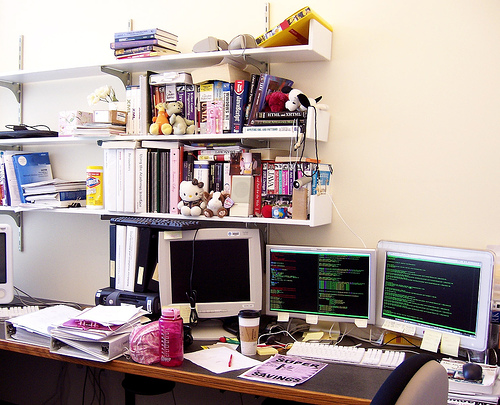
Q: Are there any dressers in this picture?
A: No, there are no dressers.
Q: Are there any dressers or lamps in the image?
A: No, there are no dressers or lamps.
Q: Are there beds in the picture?
A: No, there are no beds.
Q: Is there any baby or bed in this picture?
A: No, there are no beds or babies.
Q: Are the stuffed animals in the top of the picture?
A: Yes, the stuffed animals are in the top of the image.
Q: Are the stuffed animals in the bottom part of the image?
A: No, the stuffed animals are in the top of the image.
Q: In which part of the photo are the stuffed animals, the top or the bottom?
A: The stuffed animals are in the top of the image.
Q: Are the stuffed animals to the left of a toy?
A: Yes, the stuffed animals are to the left of a toy.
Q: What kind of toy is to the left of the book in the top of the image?
A: The toys are stuffed animals.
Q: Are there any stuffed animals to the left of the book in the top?
A: Yes, there are stuffed animals to the left of the book.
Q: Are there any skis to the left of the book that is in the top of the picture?
A: No, there are stuffed animals to the left of the book.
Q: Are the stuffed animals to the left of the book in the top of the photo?
A: Yes, the stuffed animals are to the left of the book.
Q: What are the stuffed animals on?
A: The stuffed animals are on the shelf.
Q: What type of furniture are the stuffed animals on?
A: The stuffed animals are on the shelf.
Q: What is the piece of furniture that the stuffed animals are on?
A: The piece of furniture is a shelf.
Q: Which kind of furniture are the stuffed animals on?
A: The stuffed animals are on the shelf.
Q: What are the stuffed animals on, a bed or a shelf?
A: The stuffed animals are on a shelf.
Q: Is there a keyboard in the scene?
A: Yes, there is a keyboard.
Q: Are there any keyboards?
A: Yes, there is a keyboard.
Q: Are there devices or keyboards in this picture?
A: Yes, there is a keyboard.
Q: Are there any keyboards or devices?
A: Yes, there is a keyboard.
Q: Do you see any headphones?
A: No, there are no headphones.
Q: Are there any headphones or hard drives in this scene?
A: No, there are no headphones or hard drives.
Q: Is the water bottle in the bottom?
A: Yes, the water bottle is in the bottom of the image.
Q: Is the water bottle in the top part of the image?
A: No, the water bottle is in the bottom of the image.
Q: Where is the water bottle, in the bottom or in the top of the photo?
A: The water bottle is in the bottom of the image.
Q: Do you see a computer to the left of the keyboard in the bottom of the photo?
A: No, there is a water bottle to the left of the keyboard.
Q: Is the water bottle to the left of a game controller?
A: No, the water bottle is to the left of the keyboard.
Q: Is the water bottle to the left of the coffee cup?
A: Yes, the water bottle is to the left of the coffee cup.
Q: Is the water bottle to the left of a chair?
A: No, the water bottle is to the left of the coffee cup.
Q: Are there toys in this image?
A: Yes, there is a toy.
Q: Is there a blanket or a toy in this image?
A: Yes, there is a toy.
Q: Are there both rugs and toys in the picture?
A: No, there is a toy but no rugs.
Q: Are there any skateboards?
A: No, there are no skateboards.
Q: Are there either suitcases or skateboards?
A: No, there are no skateboards or suitcases.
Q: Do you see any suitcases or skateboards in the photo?
A: No, there are no skateboards or suitcases.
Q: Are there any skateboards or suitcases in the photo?
A: No, there are no skateboards or suitcases.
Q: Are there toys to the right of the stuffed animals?
A: Yes, there is a toy to the right of the stuffed animals.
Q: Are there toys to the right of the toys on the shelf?
A: Yes, there is a toy to the right of the stuffed animals.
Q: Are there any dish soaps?
A: No, there are no dish soaps.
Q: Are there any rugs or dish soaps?
A: No, there are no dish soaps or rugs.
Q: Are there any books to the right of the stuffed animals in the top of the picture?
A: Yes, there is a book to the right of the stuffed animals.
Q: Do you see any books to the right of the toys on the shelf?
A: Yes, there is a book to the right of the stuffed animals.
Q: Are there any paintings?
A: No, there are no paintings.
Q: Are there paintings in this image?
A: No, there are no paintings.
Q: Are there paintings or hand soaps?
A: No, there are no paintings or hand soaps.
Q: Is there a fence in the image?
A: No, there are no fences.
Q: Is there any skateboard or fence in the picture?
A: No, there are no fences or skateboards.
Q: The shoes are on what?
A: The shoes are on the shelf.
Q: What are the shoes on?
A: The shoes are on the shelf.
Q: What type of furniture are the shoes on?
A: The shoes are on the shelf.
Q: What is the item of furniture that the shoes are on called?
A: The piece of furniture is a shelf.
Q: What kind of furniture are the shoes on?
A: The shoes are on the shelf.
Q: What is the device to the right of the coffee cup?
A: The device is a screen.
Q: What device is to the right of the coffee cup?
A: The device is a screen.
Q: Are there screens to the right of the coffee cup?
A: Yes, there is a screen to the right of the coffee cup.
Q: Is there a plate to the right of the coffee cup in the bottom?
A: No, there is a screen to the right of the coffee cup.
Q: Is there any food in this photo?
A: No, there is no food.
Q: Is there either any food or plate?
A: No, there are no food or plates.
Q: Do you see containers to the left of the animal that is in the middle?
A: Yes, there is a container to the left of the animal.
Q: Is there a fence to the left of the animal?
A: No, there is a container to the left of the animal.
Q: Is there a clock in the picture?
A: No, there are no clocks.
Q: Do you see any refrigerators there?
A: No, there are no refrigerators.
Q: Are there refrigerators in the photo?
A: No, there are no refrigerators.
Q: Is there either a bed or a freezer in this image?
A: No, there are no refrigerators or beds.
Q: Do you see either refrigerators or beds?
A: No, there are no refrigerators or beds.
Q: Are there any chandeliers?
A: No, there are no chandeliers.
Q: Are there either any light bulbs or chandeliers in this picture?
A: No, there are no chandeliers or light bulbs.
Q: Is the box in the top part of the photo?
A: Yes, the box is in the top of the image.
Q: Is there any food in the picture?
A: No, there is no food.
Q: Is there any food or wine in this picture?
A: No, there are no food or wines.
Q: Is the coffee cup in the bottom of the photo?
A: Yes, the coffee cup is in the bottom of the image.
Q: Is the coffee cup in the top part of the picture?
A: No, the coffee cup is in the bottom of the image.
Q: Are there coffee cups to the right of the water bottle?
A: Yes, there is a coffee cup to the right of the water bottle.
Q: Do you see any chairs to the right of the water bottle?
A: No, there is a coffee cup to the right of the water bottle.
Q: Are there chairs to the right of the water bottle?
A: No, there is a coffee cup to the right of the water bottle.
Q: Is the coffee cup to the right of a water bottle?
A: Yes, the coffee cup is to the right of a water bottle.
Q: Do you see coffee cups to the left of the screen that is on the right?
A: Yes, there is a coffee cup to the left of the screen.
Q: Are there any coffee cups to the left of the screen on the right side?
A: Yes, there is a coffee cup to the left of the screen.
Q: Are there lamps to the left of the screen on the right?
A: No, there is a coffee cup to the left of the screen.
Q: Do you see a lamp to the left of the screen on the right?
A: No, there is a coffee cup to the left of the screen.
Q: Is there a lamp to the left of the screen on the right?
A: No, there is a coffee cup to the left of the screen.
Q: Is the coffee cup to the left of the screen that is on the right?
A: Yes, the coffee cup is to the left of the screen.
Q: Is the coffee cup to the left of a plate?
A: No, the coffee cup is to the left of the screen.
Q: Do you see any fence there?
A: No, there are no fences.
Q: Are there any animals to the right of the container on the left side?
A: Yes, there is an animal to the right of the container.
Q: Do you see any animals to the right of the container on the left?
A: Yes, there is an animal to the right of the container.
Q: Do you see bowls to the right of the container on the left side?
A: No, there is an animal to the right of the container.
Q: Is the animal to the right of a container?
A: Yes, the animal is to the right of a container.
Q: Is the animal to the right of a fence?
A: No, the animal is to the right of a container.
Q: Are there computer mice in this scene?
A: Yes, there is a computer mouse.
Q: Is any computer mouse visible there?
A: Yes, there is a computer mouse.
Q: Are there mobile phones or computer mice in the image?
A: Yes, there is a computer mouse.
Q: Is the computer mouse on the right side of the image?
A: Yes, the computer mouse is on the right of the image.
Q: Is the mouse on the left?
A: No, the mouse is on the right of the image.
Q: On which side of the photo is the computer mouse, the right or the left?
A: The computer mouse is on the right of the image.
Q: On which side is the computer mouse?
A: The computer mouse is on the right of the image.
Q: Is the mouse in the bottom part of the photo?
A: Yes, the mouse is in the bottom of the image.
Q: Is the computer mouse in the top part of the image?
A: No, the computer mouse is in the bottom of the image.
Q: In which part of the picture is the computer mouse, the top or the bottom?
A: The computer mouse is in the bottom of the image.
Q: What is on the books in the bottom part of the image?
A: The mouse is on the books.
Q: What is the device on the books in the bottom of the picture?
A: The device is a computer mouse.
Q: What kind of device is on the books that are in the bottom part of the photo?
A: The device is a computer mouse.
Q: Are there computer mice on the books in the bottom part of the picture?
A: Yes, there is a computer mouse on the books.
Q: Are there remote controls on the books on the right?
A: No, there is a computer mouse on the books.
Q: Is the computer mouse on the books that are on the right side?
A: Yes, the computer mouse is on the books.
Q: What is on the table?
A: The mouse is on the table.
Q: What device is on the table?
A: The device is a computer mouse.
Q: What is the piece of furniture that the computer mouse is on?
A: The piece of furniture is a table.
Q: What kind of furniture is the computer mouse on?
A: The computer mouse is on the table.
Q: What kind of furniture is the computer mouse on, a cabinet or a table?
A: The computer mouse is on a table.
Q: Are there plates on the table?
A: No, there is a computer mouse on the table.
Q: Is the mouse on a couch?
A: No, the mouse is on the table.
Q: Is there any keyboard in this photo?
A: Yes, there is a keyboard.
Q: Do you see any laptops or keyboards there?
A: Yes, there is a keyboard.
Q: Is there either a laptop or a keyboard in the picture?
A: Yes, there is a keyboard.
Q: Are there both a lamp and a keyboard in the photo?
A: No, there is a keyboard but no lamps.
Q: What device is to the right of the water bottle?
A: The device is a keyboard.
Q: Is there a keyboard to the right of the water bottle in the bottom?
A: Yes, there is a keyboard to the right of the water bottle.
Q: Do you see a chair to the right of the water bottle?
A: No, there is a keyboard to the right of the water bottle.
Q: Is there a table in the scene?
A: Yes, there is a table.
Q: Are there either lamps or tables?
A: Yes, there is a table.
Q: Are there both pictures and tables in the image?
A: No, there is a table but no pictures.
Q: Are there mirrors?
A: No, there are no mirrors.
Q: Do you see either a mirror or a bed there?
A: No, there are no mirrors or beds.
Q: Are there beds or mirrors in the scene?
A: No, there are no mirrors or beds.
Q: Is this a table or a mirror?
A: This is a table.